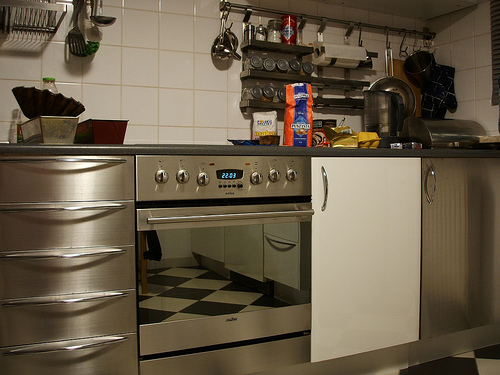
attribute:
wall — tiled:
[114, 6, 238, 138]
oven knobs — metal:
[150, 167, 307, 187]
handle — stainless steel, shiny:
[318, 166, 330, 213]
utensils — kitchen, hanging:
[71, 2, 111, 64]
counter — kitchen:
[0, 141, 500, 162]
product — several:
[282, 77, 315, 147]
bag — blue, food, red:
[269, 71, 324, 148]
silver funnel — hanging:
[211, 32, 243, 63]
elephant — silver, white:
[307, 152, 428, 367]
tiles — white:
[2, 3, 484, 144]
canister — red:
[256, 0, 337, 45]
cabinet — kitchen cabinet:
[309, 156, 420, 362]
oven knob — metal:
[284, 168, 298, 181]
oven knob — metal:
[269, 169, 280, 182]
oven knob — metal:
[250, 170, 264, 185]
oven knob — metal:
[196, 170, 209, 186]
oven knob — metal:
[175, 169, 188, 183]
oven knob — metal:
[154, 167, 169, 182]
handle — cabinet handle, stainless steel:
[0, 157, 127, 164]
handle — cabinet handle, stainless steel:
[2, 200, 126, 210]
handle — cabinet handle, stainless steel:
[3, 247, 130, 257]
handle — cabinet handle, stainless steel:
[2, 290, 129, 305]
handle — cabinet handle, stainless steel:
[1, 334, 126, 354]